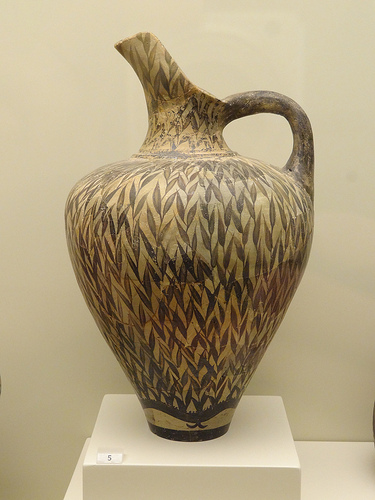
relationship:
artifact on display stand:
[40, 48, 338, 451] [95, 444, 299, 493]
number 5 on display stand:
[80, 449, 131, 476] [95, 444, 299, 493]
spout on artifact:
[113, 33, 176, 92] [40, 48, 338, 451]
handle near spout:
[226, 95, 321, 173] [113, 33, 176, 92]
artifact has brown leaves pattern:
[40, 48, 338, 451] [167, 185, 246, 221]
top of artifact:
[118, 35, 173, 58] [40, 48, 338, 451]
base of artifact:
[121, 393, 259, 453] [40, 48, 338, 451]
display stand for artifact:
[95, 444, 299, 493] [40, 48, 338, 451]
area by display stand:
[287, 400, 371, 475] [95, 444, 299, 493]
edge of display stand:
[273, 387, 300, 415] [95, 444, 299, 493]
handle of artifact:
[226, 95, 321, 173] [40, 48, 338, 451]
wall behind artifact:
[292, 25, 336, 53] [40, 48, 338, 451]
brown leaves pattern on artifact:
[167, 185, 246, 221] [40, 48, 338, 451]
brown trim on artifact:
[144, 399, 272, 421] [40, 48, 338, 451]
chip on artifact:
[101, 35, 130, 49] [40, 48, 338, 451]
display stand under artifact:
[95, 444, 299, 493] [40, 48, 338, 451]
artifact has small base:
[40, 48, 338, 451] [146, 435, 237, 449]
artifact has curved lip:
[40, 48, 338, 451] [141, 34, 181, 45]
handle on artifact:
[226, 95, 321, 173] [40, 48, 338, 451]